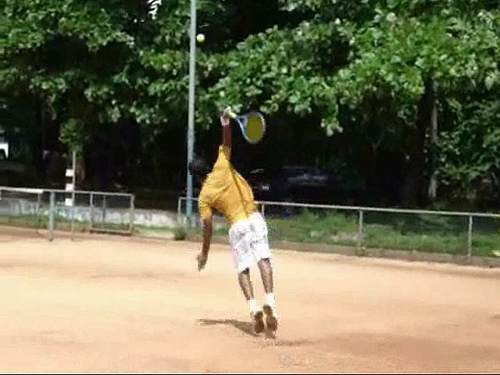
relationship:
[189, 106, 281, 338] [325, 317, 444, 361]
ball player playing on court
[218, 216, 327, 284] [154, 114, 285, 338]
shorts on man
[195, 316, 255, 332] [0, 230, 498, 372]
shadow on ground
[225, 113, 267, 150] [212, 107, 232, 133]
racket in hand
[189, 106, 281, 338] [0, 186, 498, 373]
ball player playing on court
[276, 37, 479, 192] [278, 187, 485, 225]
trees behind fence